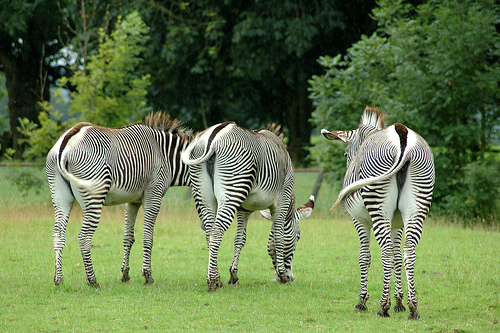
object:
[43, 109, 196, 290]
zebra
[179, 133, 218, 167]
tail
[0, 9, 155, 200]
plants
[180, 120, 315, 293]
zebra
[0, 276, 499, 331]
grass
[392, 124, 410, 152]
stripe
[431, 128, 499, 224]
bush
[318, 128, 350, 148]
left ear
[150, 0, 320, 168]
trees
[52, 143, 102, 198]
tail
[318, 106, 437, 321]
ebra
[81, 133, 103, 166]
prints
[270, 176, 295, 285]
arm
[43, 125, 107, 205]
zebra butt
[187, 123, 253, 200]
zebra butt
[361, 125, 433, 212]
zebra butt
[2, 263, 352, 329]
field